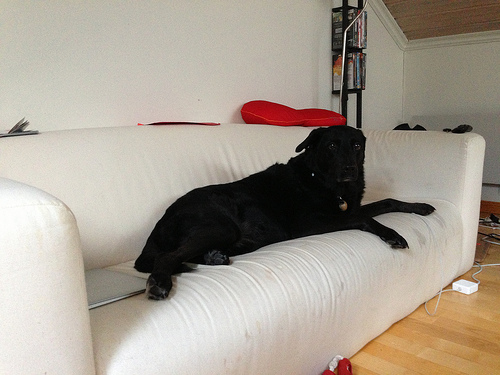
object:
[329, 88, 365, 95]
shelf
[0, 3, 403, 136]
wall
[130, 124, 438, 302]
black dog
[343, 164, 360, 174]
nose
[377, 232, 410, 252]
paws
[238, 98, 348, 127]
red pillow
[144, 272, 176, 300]
feet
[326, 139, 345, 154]
eye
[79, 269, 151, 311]
laptop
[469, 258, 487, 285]
wires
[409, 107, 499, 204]
shadow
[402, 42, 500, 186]
wall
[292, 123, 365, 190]
head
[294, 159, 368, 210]
collar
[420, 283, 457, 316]
power cord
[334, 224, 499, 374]
floor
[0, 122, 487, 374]
couch